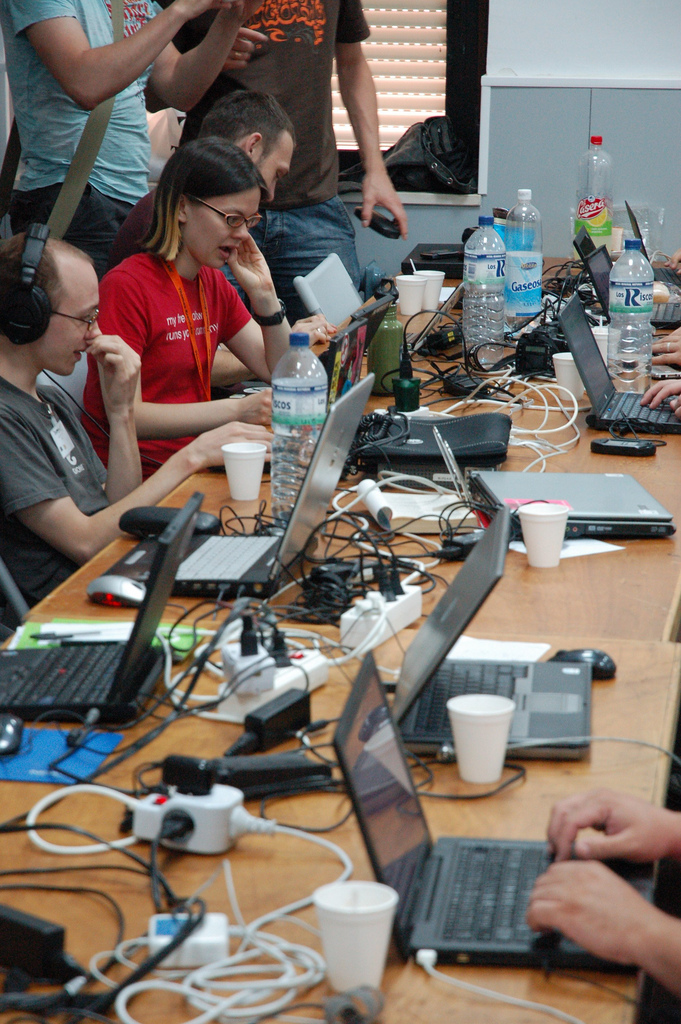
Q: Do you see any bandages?
A: No, there are no bandages.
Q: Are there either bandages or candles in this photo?
A: No, there are no bandages or candles.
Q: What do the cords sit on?
A: The wires sit on the table.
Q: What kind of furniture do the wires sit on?
A: The wires sit on the table.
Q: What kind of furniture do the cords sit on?
A: The wires sit on the table.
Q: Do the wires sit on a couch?
A: No, the wires sit on a table.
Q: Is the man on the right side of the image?
A: Yes, the man is on the right of the image.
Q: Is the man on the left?
A: No, the man is on the right of the image.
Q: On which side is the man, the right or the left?
A: The man is on the right of the image.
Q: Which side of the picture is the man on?
A: The man is on the right of the image.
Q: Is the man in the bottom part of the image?
A: Yes, the man is in the bottom of the image.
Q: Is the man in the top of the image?
A: No, the man is in the bottom of the image.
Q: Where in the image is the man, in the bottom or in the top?
A: The man is in the bottom of the image.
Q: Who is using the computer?
A: The man is using the computer.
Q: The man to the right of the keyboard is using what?
A: The man is using a computer.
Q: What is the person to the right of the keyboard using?
A: The man is using a computer.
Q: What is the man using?
A: The man is using a computer.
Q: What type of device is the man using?
A: The man is using a computer.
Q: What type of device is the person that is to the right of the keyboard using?
A: The man is using a computer.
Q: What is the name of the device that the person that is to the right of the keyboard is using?
A: The device is a computer.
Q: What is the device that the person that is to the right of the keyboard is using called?
A: The device is a computer.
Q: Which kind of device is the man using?
A: The man is using a computer.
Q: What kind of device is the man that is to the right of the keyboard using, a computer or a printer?
A: The man is using a computer.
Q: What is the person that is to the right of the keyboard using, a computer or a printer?
A: The man is using a computer.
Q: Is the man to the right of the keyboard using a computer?
A: Yes, the man is using a computer.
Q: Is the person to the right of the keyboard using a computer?
A: Yes, the man is using a computer.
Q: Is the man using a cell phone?
A: No, the man is using a computer.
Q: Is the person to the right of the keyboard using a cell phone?
A: No, the man is using a computer.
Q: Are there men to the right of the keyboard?
A: Yes, there is a man to the right of the keyboard.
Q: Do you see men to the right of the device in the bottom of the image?
A: Yes, there is a man to the right of the keyboard.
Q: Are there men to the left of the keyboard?
A: No, the man is to the right of the keyboard.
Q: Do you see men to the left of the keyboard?
A: No, the man is to the right of the keyboard.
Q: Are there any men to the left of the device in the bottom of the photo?
A: No, the man is to the right of the keyboard.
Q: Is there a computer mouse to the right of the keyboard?
A: No, there is a man to the right of the keyboard.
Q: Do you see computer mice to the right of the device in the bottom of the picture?
A: No, there is a man to the right of the keyboard.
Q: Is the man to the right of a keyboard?
A: Yes, the man is to the right of a keyboard.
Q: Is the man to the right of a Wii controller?
A: No, the man is to the right of a keyboard.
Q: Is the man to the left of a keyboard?
A: No, the man is to the right of a keyboard.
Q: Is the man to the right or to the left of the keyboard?
A: The man is to the right of the keyboard.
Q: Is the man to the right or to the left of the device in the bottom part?
A: The man is to the right of the keyboard.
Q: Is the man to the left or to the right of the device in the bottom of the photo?
A: The man is to the right of the keyboard.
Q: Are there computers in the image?
A: Yes, there is a computer.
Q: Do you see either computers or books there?
A: Yes, there is a computer.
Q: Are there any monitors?
A: No, there are no monitors.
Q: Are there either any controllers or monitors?
A: No, there are no monitors or controllers.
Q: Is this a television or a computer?
A: This is a computer.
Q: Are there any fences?
A: No, there are no fences.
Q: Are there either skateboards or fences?
A: No, there are no fences or skateboards.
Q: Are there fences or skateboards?
A: No, there are no fences or skateboards.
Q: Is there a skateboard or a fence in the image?
A: No, there are no fences or skateboards.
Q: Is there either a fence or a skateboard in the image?
A: No, there are no fences or skateboards.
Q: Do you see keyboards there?
A: Yes, there is a keyboard.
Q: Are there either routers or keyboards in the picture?
A: Yes, there is a keyboard.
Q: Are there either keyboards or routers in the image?
A: Yes, there is a keyboard.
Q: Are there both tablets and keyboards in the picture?
A: No, there is a keyboard but no tablets.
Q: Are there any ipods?
A: No, there are no ipods.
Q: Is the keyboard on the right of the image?
A: Yes, the keyboard is on the right of the image.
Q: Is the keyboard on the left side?
A: No, the keyboard is on the right of the image.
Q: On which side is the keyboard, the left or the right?
A: The keyboard is on the right of the image.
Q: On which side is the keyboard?
A: The keyboard is on the right of the image.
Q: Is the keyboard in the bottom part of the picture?
A: Yes, the keyboard is in the bottom of the image.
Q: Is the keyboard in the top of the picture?
A: No, the keyboard is in the bottom of the image.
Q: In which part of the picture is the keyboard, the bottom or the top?
A: The keyboard is in the bottom of the image.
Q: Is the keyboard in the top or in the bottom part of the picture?
A: The keyboard is in the bottom of the image.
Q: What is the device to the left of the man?
A: The device is a keyboard.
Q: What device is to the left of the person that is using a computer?
A: The device is a keyboard.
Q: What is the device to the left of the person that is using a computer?
A: The device is a keyboard.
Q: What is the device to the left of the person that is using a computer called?
A: The device is a keyboard.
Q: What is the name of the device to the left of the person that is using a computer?
A: The device is a keyboard.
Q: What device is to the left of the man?
A: The device is a keyboard.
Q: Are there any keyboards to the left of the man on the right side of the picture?
A: Yes, there is a keyboard to the left of the man.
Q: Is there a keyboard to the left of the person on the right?
A: Yes, there is a keyboard to the left of the man.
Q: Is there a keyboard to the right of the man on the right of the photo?
A: No, the keyboard is to the left of the man.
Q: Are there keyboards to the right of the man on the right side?
A: No, the keyboard is to the left of the man.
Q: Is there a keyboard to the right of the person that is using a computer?
A: No, the keyboard is to the left of the man.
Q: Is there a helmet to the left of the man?
A: No, there is a keyboard to the left of the man.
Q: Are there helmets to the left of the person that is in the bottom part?
A: No, there is a keyboard to the left of the man.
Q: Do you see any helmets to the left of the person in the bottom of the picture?
A: No, there is a keyboard to the left of the man.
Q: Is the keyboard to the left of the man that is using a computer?
A: Yes, the keyboard is to the left of the man.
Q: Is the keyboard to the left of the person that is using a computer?
A: Yes, the keyboard is to the left of the man.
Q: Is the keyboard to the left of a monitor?
A: No, the keyboard is to the left of the man.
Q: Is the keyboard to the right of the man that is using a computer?
A: No, the keyboard is to the left of the man.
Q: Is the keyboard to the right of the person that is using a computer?
A: No, the keyboard is to the left of the man.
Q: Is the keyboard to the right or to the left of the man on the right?
A: The keyboard is to the left of the man.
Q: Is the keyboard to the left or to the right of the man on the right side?
A: The keyboard is to the left of the man.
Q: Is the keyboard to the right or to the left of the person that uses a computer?
A: The keyboard is to the left of the man.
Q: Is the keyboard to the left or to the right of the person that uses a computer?
A: The keyboard is to the left of the man.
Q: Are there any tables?
A: Yes, there is a table.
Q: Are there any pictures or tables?
A: Yes, there is a table.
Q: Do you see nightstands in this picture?
A: No, there are no nightstands.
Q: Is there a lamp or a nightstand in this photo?
A: No, there are no nightstands or lamps.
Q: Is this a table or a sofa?
A: This is a table.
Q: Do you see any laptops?
A: Yes, there is a laptop.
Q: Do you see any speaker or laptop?
A: Yes, there is a laptop.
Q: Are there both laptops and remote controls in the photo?
A: No, there is a laptop but no remote controls.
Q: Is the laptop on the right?
A: Yes, the laptop is on the right of the image.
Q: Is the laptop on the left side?
A: No, the laptop is on the right of the image.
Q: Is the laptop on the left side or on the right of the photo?
A: The laptop is on the right of the image.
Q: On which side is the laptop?
A: The laptop is on the right of the image.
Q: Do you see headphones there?
A: Yes, there are headphones.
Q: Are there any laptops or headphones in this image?
A: Yes, there are headphones.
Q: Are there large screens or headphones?
A: Yes, there are large headphones.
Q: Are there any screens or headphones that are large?
A: Yes, the headphones are large.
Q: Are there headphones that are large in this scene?
A: Yes, there are large headphones.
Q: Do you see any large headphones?
A: Yes, there are large headphones.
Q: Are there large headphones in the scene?
A: Yes, there are large headphones.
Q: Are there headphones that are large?
A: Yes, there are headphones that are large.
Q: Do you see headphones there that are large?
A: Yes, there are headphones that are large.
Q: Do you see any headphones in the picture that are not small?
A: Yes, there are large headphones.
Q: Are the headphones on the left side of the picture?
A: Yes, the headphones are on the left of the image.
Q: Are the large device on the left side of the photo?
A: Yes, the headphones are on the left of the image.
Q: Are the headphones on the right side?
A: No, the headphones are on the left of the image.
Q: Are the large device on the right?
A: No, the headphones are on the left of the image.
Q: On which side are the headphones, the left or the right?
A: The headphones are on the left of the image.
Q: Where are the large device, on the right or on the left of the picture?
A: The headphones are on the left of the image.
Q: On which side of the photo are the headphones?
A: The headphones are on the left of the image.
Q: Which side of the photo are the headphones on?
A: The headphones are on the left of the image.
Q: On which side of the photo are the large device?
A: The headphones are on the left of the image.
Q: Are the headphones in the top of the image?
A: Yes, the headphones are in the top of the image.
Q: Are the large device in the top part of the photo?
A: Yes, the headphones are in the top of the image.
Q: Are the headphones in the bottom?
A: No, the headphones are in the top of the image.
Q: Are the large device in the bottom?
A: No, the headphones are in the top of the image.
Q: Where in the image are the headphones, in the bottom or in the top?
A: The headphones are in the top of the image.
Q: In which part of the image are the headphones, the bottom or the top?
A: The headphones are in the top of the image.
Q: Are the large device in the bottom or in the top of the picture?
A: The headphones are in the top of the image.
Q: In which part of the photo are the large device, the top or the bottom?
A: The headphones are in the top of the image.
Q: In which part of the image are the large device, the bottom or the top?
A: The headphones are in the top of the image.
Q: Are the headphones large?
A: Yes, the headphones are large.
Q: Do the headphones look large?
A: Yes, the headphones are large.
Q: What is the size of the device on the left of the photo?
A: The headphones are large.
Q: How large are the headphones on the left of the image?
A: The headphones are large.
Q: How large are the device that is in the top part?
A: The headphones are large.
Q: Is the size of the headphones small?
A: No, the headphones are large.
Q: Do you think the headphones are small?
A: No, the headphones are large.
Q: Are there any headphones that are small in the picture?
A: No, there are headphones but they are large.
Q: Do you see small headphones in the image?
A: No, there are headphones but they are large.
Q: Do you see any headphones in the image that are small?
A: No, there are headphones but they are large.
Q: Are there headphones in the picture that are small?
A: No, there are headphones but they are large.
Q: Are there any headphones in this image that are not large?
A: No, there are headphones but they are large.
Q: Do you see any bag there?
A: Yes, there is a bag.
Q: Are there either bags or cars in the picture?
A: Yes, there is a bag.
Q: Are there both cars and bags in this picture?
A: No, there is a bag but no cars.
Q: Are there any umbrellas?
A: No, there are no umbrellas.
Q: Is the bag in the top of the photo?
A: Yes, the bag is in the top of the image.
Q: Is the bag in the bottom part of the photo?
A: No, the bag is in the top of the image.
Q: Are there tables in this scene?
A: Yes, there is a table.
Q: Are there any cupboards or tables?
A: Yes, there is a table.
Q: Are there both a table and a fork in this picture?
A: No, there is a table but no forks.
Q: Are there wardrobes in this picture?
A: No, there are no wardrobes.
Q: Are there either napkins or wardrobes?
A: No, there are no wardrobes or napkins.